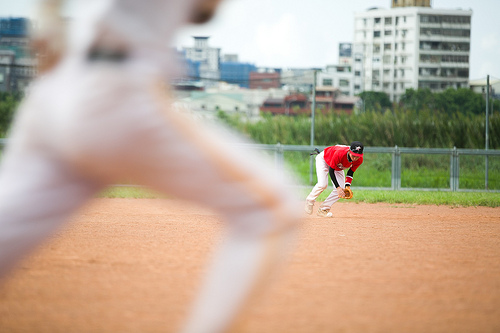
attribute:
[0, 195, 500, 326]
field — brown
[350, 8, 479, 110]
building — windowed, tall, far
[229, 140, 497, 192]
fence — metal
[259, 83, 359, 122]
building — brick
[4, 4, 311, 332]
player — white, running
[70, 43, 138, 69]
belt — black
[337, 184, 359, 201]
glove — here, brown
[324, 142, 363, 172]
shirt — red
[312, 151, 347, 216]
pants — white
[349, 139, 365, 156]
hat — black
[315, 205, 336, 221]
shoe — white